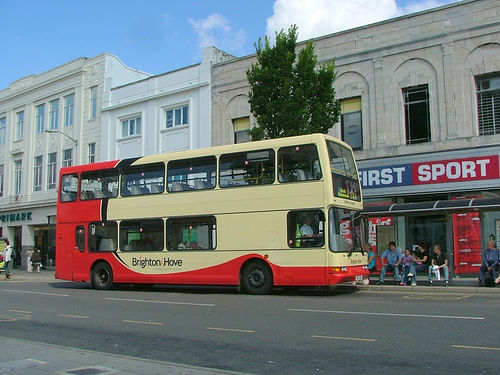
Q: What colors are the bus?
A: Yellow and Red.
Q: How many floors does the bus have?
A: 2.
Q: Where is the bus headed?
A: To the right.